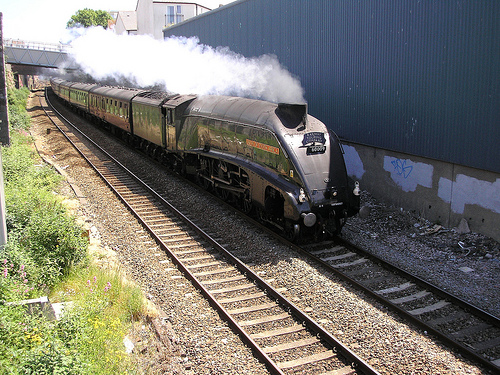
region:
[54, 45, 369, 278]
the train is black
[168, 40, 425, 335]
the train is black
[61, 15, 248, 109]
the smoke is white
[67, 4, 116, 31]
green tree in behind the back of a train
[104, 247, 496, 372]
two train tracks on gray gravel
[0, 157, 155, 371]
green grass and shrubs next to train tracks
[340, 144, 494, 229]
white patches on a gray cement foundation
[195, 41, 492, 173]
blue side of a building with verticle lines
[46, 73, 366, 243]
gray and black train running on a track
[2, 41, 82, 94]
gray bridge over two train tracks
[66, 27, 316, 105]
white exhaust from a train engine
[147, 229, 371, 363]
steel rails over wooden railroad ties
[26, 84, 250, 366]
gray gravel along side of train track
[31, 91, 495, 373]
gray metal train tracks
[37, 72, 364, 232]
large black train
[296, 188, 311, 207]
small front right light of train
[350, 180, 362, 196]
small left front light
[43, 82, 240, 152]
bunch of windows on right side of train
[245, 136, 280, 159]
orange label in the front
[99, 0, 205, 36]
white building in the back of the fence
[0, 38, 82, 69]
bridge with gray rails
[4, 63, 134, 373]
green bushes in the left side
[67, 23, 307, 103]
white smoke in the top of the train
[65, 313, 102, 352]
Small patch of green grass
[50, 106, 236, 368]
Dark brown railroad tracks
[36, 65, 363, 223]
Very long steam engine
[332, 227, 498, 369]
PArt of brown tracks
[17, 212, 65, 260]
Small patch of green grass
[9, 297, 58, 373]
Small patch of green grass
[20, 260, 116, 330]
Small patch of green grass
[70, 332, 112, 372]
Small patch of green grass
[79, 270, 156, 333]
Small patch of green grass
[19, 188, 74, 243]
Small patch of green grass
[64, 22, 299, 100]
big white cloud of smoke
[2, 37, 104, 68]
little bridge with gray metal rails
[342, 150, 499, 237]
gray brick wall with white brushes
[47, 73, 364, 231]
black large train on train tracks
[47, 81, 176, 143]
a bunch of windows in the left side of the train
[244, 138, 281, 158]
orange label in front of the train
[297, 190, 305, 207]
little front right light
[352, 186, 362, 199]
little front right light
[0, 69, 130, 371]
light green bushes